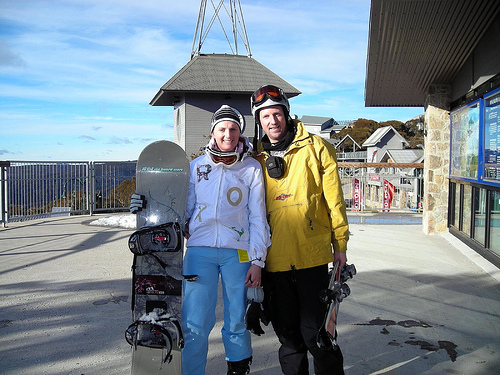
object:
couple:
[130, 84, 350, 374]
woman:
[129, 104, 273, 375]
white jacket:
[183, 152, 273, 269]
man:
[250, 84, 350, 375]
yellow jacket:
[252, 120, 350, 273]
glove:
[129, 193, 147, 214]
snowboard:
[124, 139, 191, 375]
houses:
[299, 115, 424, 214]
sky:
[1, 0, 425, 164]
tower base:
[188, 0, 253, 59]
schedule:
[482, 95, 500, 181]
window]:
[447, 89, 500, 271]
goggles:
[252, 89, 278, 103]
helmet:
[250, 84, 290, 124]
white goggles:
[205, 148, 241, 169]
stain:
[347, 317, 460, 366]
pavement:
[1, 212, 500, 374]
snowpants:
[179, 246, 251, 375]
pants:
[259, 262, 347, 375]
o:
[226, 186, 244, 207]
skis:
[315, 260, 357, 351]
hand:
[332, 250, 347, 269]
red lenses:
[254, 90, 278, 103]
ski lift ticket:
[237, 248, 249, 263]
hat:
[209, 108, 241, 134]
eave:
[363, 0, 500, 108]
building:
[362, 0, 499, 283]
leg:
[181, 260, 218, 375]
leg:
[299, 271, 345, 375]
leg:
[223, 250, 256, 373]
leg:
[261, 269, 312, 375]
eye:
[219, 127, 225, 133]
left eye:
[229, 128, 236, 131]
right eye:
[263, 113, 269, 118]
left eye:
[273, 113, 280, 117]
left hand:
[244, 264, 261, 288]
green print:
[140, 167, 184, 173]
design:
[195, 163, 212, 183]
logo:
[275, 193, 291, 202]